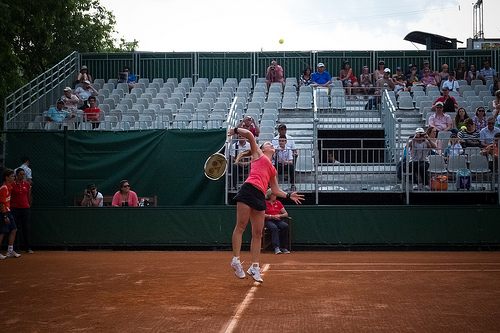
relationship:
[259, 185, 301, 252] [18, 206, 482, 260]
person by partition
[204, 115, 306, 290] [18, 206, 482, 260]
person by partition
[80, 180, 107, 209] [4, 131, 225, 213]
people seated by wall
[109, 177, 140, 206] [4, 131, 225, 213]
people seated by wall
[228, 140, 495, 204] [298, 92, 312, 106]
railing in front of seat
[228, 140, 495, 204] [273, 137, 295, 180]
railing in front of spectator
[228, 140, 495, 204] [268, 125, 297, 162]
railing in front of spectator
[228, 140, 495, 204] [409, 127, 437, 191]
railing in front of person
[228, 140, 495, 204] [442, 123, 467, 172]
railing in front of spectator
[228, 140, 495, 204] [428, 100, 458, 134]
railing in front of person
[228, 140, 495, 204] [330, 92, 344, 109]
railing in front of seat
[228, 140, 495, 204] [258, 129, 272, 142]
railing in front of seat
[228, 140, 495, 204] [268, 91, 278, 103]
railing in front of seat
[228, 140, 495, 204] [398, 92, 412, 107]
railing in front of seat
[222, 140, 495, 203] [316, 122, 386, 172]
railing around passageway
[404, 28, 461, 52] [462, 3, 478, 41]
slanted structure by columns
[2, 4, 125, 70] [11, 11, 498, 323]
tree higher than stadium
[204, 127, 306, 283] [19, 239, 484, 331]
person on court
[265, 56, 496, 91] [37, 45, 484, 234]
people in stands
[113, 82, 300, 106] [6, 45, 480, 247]
seats in stands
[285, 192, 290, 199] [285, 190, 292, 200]
band on wrist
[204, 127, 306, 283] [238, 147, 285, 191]
person wearing top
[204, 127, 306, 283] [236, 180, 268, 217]
person wearing skirt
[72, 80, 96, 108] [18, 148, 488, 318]
person watching tennis match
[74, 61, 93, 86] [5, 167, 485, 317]
person watching tennis match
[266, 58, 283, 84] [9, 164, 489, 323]
person watching match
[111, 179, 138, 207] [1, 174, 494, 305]
people watching tennis match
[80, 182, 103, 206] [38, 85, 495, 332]
people watching tennis match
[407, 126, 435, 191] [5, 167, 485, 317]
person watching tennis match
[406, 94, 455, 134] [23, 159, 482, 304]
person watching tennis match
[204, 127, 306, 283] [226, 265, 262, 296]
person in mid-jump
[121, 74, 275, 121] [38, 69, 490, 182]
chairs in bleachers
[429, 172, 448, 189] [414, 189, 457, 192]
bag on floor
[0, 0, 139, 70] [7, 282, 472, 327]
tree overlooks field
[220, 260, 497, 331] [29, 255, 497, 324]
lines on court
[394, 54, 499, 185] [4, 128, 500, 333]
spectators watching tennis match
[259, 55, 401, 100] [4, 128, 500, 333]
spectators watching tennis match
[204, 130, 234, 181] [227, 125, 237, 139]
racket in hand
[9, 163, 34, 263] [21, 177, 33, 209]
person wearing shirt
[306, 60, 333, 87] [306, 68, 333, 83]
man wearing blue shirt